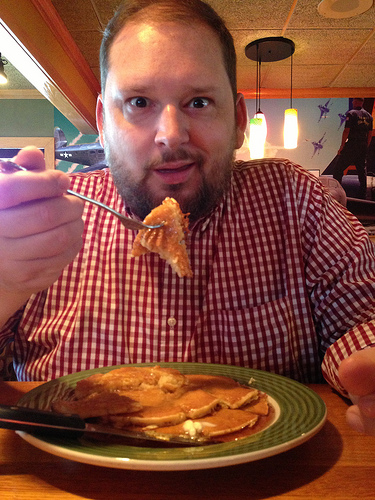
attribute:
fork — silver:
[1, 157, 166, 242]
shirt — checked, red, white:
[0, 155, 374, 386]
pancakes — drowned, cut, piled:
[73, 352, 267, 435]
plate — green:
[8, 356, 331, 476]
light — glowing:
[281, 103, 303, 153]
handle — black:
[0, 400, 84, 445]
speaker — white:
[317, 1, 374, 24]